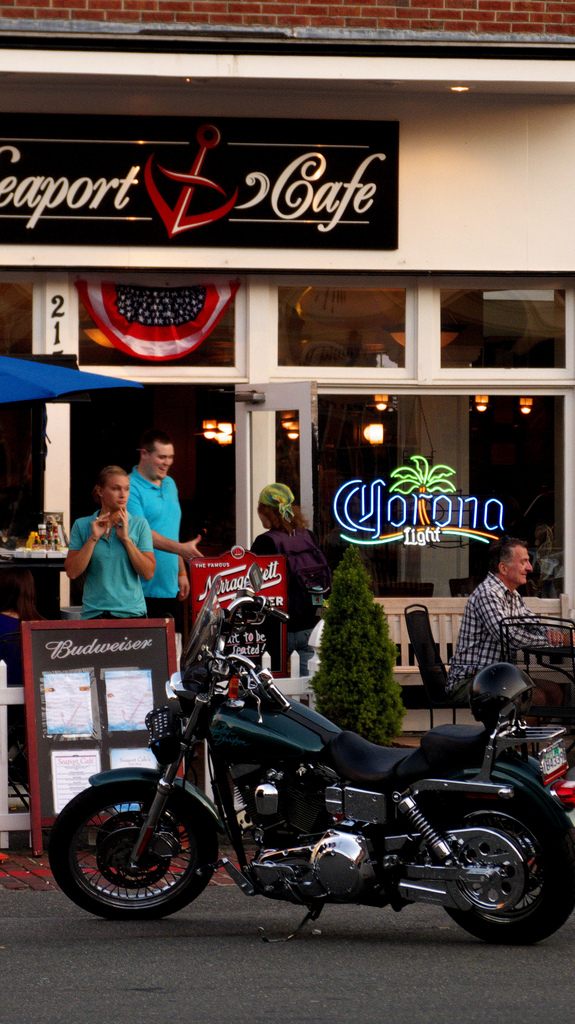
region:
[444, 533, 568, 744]
man in a checked shirt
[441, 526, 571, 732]
man sitting at a table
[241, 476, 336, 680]
person with a purple backpack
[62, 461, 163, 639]
woman with a blue shirt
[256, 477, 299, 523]
bandana on a person's head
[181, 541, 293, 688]
red sign on the sidewalk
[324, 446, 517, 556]
beer sign on the window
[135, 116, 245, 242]
painting of anchor on sign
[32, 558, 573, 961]
black motorcycle is parked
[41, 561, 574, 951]
parked motorcyle is black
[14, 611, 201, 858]
menu board behind motorcycle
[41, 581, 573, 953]
motorcycle parked in front of a restaurant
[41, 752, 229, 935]
front wheel of motorcycle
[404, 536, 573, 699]
man in plaid shirt sitting at table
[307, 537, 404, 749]
small green evergreen growing in front of restaurant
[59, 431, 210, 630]
man and woman in blue shirts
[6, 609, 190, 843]
board with menus and Budweiser written at top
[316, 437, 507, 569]
neon sign with palm tree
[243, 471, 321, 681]
woman in purple entering restaurant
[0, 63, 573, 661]
front of restaurant called Seaport Cafe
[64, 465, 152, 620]
The woman is wearing a t-shirt.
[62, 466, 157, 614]
The woman is wearing a blue t-shirt.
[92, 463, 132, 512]
The woman has blonde hair.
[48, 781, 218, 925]
The front motorcycle wheel is round in shape.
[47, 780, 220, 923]
The front motorcycle wheel is black in color.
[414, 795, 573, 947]
The back motorcycle wheel is black in color.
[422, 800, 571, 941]
The back motorcycle wheel is round in shape.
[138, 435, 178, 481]
The man has brown hair.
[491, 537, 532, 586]
The man has black and gray hair.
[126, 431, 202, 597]
The man is wearing a blue t-shirt.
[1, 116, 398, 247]
Seaport Cafe sign on building